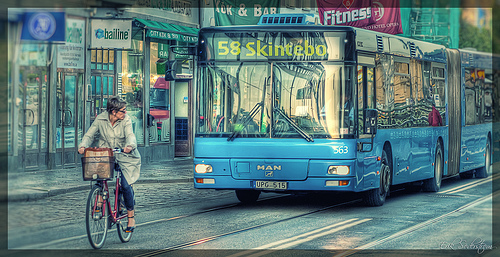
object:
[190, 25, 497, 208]
bus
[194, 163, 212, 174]
light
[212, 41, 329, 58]
yellow letters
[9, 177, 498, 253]
road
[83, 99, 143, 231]
woman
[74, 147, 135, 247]
bike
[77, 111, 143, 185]
jacket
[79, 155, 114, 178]
basket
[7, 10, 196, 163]
shops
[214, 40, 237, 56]
number 58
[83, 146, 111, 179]
bag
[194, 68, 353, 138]
windshield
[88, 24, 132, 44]
sign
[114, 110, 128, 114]
glasses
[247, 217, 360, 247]
lines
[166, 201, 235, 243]
tracks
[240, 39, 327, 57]
words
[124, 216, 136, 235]
high heels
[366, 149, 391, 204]
tire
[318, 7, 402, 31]
advertising sign